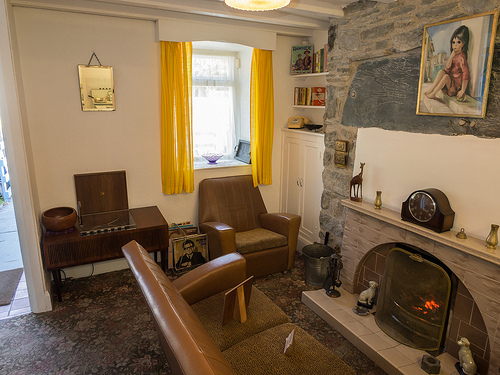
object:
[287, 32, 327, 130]
bookshelf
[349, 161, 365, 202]
figurine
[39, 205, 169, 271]
desk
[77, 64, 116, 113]
plaque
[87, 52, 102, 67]
string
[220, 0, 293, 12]
fixture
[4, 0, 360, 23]
ceiling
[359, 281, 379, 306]
animal figurine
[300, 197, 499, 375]
fireplace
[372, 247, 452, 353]
fireplace guard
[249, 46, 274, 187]
curtains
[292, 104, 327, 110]
shelf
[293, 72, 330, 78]
shelf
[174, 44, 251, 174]
window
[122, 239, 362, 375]
couch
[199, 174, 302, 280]
armchair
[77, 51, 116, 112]
mirror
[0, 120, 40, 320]
door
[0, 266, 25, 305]
brown mat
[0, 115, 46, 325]
outside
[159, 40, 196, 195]
curtains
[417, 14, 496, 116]
painting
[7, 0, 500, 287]
wall